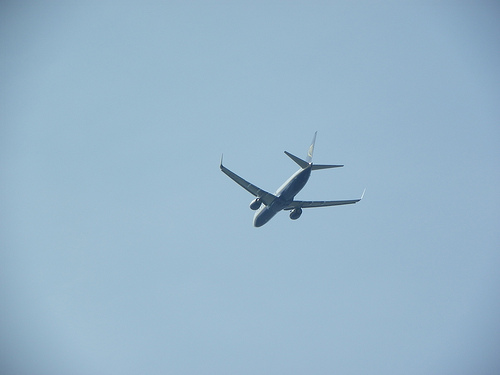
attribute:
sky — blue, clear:
[1, 0, 499, 373]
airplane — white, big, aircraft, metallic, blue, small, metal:
[219, 130, 366, 228]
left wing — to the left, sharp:
[217, 153, 274, 209]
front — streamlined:
[250, 200, 278, 229]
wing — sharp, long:
[292, 194, 367, 215]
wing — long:
[213, 151, 278, 207]